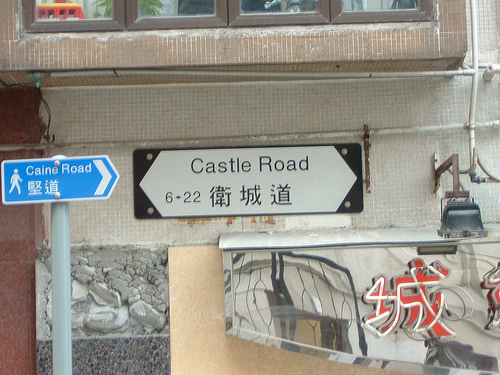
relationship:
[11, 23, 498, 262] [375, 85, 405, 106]
building has tile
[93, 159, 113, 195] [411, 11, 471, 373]
arrow points right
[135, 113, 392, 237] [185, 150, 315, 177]
sign shows castle road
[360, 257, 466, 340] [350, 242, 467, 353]
chinese shows chinese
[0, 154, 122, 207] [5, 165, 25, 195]
sign shows person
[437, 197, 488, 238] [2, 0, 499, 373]
headlight on building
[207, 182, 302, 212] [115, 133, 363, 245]
characters on sign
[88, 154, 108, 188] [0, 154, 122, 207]
arrow on sign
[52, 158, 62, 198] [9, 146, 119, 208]
rivets on sign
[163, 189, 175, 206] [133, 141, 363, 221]
6 on sign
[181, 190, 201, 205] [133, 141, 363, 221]
22 on sign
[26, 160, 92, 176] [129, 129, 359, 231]
caine road on sign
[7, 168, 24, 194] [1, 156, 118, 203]
person on sign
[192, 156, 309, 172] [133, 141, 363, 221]
castle road on sign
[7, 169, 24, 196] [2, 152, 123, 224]
person on sign